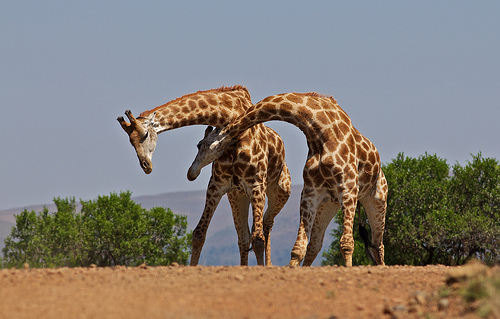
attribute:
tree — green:
[372, 150, 498, 267]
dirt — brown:
[0, 269, 498, 316]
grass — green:
[446, 274, 491, 306]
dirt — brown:
[30, 272, 494, 315]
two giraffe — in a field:
[118, 86, 391, 264]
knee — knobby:
[247, 220, 268, 253]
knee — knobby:
[340, 232, 359, 256]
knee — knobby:
[186, 226, 207, 246]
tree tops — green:
[4, 190, 191, 266]